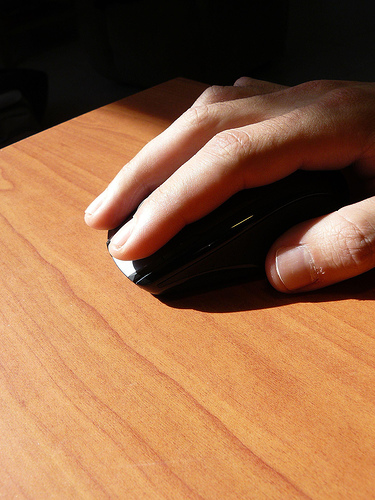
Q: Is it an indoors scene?
A: Yes, it is indoors.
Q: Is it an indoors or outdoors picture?
A: It is indoors.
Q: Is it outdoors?
A: No, it is indoors.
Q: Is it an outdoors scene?
A: No, it is indoors.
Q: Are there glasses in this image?
A: No, there are no glasses.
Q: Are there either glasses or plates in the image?
A: No, there are no glasses or plates.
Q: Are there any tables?
A: Yes, there is a table.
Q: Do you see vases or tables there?
A: Yes, there is a table.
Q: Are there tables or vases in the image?
A: Yes, there is a table.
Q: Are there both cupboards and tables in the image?
A: No, there is a table but no cupboards.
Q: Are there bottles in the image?
A: No, there are no bottles.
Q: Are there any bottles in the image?
A: No, there are no bottles.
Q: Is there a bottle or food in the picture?
A: No, there are no bottles or food.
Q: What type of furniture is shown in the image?
A: The furniture is a table.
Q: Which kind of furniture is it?
A: The piece of furniture is a table.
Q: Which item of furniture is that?
A: This is a table.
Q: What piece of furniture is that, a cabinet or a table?
A: This is a table.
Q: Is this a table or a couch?
A: This is a table.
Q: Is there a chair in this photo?
A: No, there are no chairs.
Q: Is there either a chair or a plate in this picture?
A: No, there are no chairs or plates.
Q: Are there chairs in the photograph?
A: No, there are no chairs.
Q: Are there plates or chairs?
A: No, there are no chairs or plates.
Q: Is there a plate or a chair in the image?
A: No, there are no chairs or plates.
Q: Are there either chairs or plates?
A: No, there are no chairs or plates.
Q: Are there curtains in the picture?
A: No, there are no curtains.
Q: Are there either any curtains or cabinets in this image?
A: No, there are no curtains or cabinets.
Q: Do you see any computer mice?
A: Yes, there is a computer mouse.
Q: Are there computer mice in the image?
A: Yes, there is a computer mouse.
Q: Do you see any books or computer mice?
A: Yes, there is a computer mouse.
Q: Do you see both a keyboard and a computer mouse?
A: No, there is a computer mouse but no keyboards.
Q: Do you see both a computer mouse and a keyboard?
A: No, there is a computer mouse but no keyboards.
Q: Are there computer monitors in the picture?
A: No, there are no computer monitors.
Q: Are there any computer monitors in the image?
A: No, there are no computer monitors.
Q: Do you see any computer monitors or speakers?
A: No, there are no computer monitors or speakers.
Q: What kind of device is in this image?
A: The device is a computer mouse.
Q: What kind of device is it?
A: The device is a computer mouse.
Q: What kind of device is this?
A: This is a computer mouse.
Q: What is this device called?
A: This is a computer mouse.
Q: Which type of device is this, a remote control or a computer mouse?
A: This is a computer mouse.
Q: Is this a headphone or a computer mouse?
A: This is a computer mouse.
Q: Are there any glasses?
A: No, there are no glasses.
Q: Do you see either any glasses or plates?
A: No, there are no glasses or plates.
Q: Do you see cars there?
A: No, there are no cars.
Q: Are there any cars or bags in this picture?
A: No, there are no cars or bags.